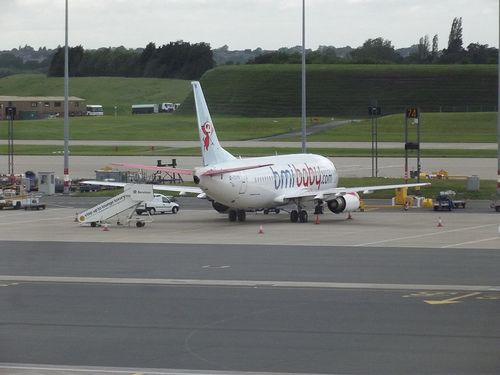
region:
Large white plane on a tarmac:
[185, 83, 430, 222]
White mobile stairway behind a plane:
[70, 182, 153, 229]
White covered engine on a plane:
[335, 191, 360, 210]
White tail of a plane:
[192, 79, 234, 171]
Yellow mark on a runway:
[410, 283, 478, 306]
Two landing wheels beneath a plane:
[291, 208, 308, 224]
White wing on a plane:
[309, 180, 429, 196]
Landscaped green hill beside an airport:
[187, 65, 499, 114]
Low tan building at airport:
[3, 93, 88, 114]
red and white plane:
[180, 79, 348, 221]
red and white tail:
[176, 84, 237, 190]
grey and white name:
[252, 157, 334, 187]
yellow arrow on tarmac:
[385, 266, 491, 353]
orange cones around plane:
[162, 200, 443, 241]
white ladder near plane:
[72, 153, 158, 223]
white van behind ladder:
[142, 189, 181, 221]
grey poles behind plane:
[272, 10, 311, 177]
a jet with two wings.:
[76, 73, 433, 223]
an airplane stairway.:
[69, 178, 159, 238]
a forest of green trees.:
[47, 37, 217, 88]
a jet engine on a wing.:
[321, 184, 364, 216]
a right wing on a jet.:
[274, 175, 436, 196]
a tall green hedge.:
[173, 62, 496, 119]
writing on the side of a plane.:
[263, 158, 328, 198]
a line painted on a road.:
[1, 274, 495, 299]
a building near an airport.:
[0, 91, 96, 127]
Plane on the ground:
[103, 79, 431, 229]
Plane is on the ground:
[103, 74, 434, 229]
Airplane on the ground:
[74, 68, 436, 227]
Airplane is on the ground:
[67, 67, 436, 233]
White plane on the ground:
[71, 72, 431, 232]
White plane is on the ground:
[75, 72, 430, 227]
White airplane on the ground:
[70, 73, 435, 231]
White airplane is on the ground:
[63, 73, 437, 230]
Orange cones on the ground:
[431, 212, 449, 231]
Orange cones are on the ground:
[432, 212, 445, 233]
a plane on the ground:
[124, 113, 352, 297]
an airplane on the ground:
[159, 109, 461, 294]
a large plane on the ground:
[146, 94, 356, 240]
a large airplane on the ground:
[142, 96, 372, 195]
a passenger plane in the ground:
[166, 101, 364, 221]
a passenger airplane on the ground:
[114, 75, 340, 229]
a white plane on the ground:
[153, 71, 419, 272]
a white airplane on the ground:
[179, 69, 364, 241]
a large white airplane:
[141, 75, 393, 265]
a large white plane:
[155, 94, 465, 336]